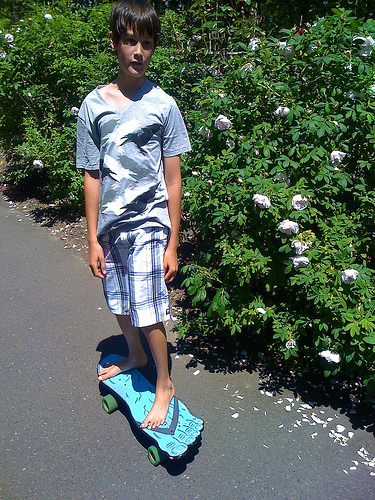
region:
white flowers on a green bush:
[236, 134, 346, 279]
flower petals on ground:
[261, 393, 367, 440]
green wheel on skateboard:
[125, 444, 166, 478]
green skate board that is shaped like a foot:
[94, 364, 195, 470]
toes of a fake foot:
[161, 415, 207, 467]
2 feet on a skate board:
[67, 342, 187, 443]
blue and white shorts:
[136, 217, 207, 333]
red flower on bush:
[239, 10, 320, 77]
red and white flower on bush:
[200, 29, 344, 161]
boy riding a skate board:
[68, 21, 181, 442]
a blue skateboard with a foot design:
[91, 330, 228, 470]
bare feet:
[91, 327, 185, 436]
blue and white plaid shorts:
[87, 216, 185, 328]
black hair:
[101, 4, 176, 35]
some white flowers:
[244, 183, 349, 371]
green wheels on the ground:
[95, 390, 174, 489]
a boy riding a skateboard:
[75, 0, 252, 472]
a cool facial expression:
[97, 7, 179, 82]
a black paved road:
[11, 232, 80, 400]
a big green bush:
[178, 54, 359, 380]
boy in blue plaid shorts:
[77, 8, 183, 325]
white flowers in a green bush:
[252, 183, 316, 267]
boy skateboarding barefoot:
[81, 3, 219, 466]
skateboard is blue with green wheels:
[98, 353, 204, 466]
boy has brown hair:
[106, 2, 161, 78]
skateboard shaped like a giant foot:
[95, 350, 203, 458]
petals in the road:
[226, 372, 370, 463]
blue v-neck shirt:
[63, 77, 194, 241]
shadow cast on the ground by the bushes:
[0, 178, 79, 238]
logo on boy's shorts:
[165, 305, 171, 314]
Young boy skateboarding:
[75, 3, 190, 427]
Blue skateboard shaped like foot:
[95, 352, 201, 462]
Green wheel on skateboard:
[142, 440, 162, 463]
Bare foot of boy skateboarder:
[137, 379, 173, 432]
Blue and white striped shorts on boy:
[92, 225, 168, 323]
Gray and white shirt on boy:
[75, 92, 184, 223]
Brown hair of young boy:
[99, 1, 164, 31]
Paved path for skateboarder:
[2, 202, 371, 496]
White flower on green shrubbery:
[275, 215, 302, 237]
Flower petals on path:
[326, 421, 354, 445]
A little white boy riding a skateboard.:
[74, 0, 204, 468]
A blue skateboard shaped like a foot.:
[95, 350, 202, 464]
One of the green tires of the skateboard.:
[100, 392, 121, 412]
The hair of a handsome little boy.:
[107, 0, 160, 49]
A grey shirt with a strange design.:
[74, 76, 192, 237]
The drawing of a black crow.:
[117, 121, 164, 156]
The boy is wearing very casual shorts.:
[99, 222, 170, 328]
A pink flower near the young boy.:
[251, 192, 271, 210]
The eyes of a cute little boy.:
[123, 35, 153, 47]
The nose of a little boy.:
[132, 43, 144, 58]